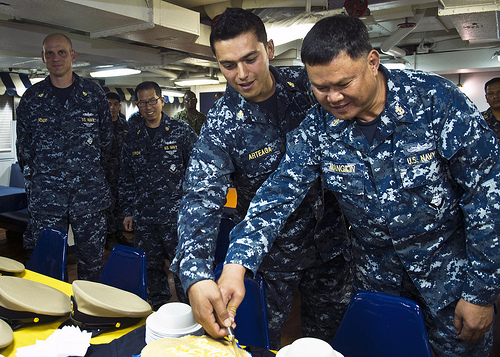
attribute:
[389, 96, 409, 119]
insignia — navy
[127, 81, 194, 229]
man — standing, looking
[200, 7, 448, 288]
men — cutting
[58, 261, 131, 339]
hats — tan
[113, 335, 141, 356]
table — yellow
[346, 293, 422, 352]
chairs — blue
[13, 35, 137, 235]
man — bald, looking